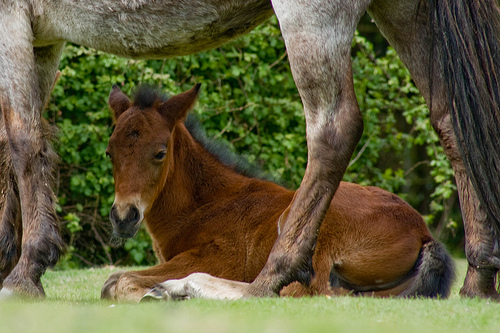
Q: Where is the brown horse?
A: Laying in the grass.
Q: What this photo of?
A: Animals.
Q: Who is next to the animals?
A: Noone.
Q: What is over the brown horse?
A: Another horse.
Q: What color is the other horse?
A: Grey.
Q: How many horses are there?
A: Two.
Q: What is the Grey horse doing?
A: Standing.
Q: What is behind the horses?
A: Bushes.